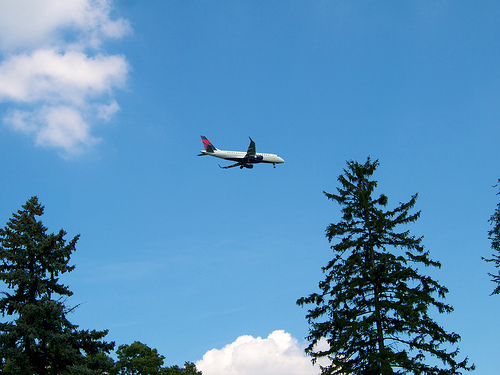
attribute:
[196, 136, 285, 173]
airplane — white, large, blue, red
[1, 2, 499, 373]
sky — light blue, blue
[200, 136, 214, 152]
tail fin — blue, red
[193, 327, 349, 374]
cloud — white, puffy, billowy, fluffy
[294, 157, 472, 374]
tree — pine, tall, sparse, slightly bent, green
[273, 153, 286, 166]
nose — white